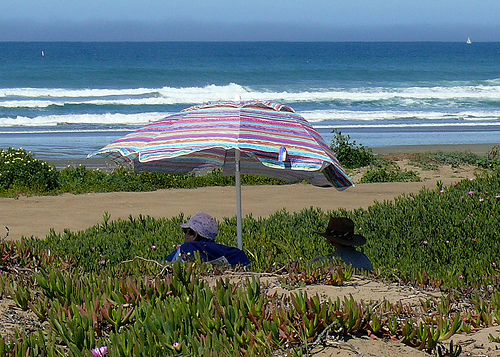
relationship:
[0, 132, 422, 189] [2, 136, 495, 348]
plants on beach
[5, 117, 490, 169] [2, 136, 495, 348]
shore on beach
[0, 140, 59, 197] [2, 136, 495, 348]
bush on beach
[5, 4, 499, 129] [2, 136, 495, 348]
ocean on beach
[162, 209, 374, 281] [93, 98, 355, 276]
people under an umbrella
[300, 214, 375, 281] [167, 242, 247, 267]
man wearing shirt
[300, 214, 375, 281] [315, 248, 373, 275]
man wearing shirt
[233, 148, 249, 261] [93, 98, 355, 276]
pole for an umbrella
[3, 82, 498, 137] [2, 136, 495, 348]
waves crashing on beach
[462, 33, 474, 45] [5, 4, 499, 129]
sail boat on ocean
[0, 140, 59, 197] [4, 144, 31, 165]
bush has white buds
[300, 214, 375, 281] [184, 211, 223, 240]
man wearing hat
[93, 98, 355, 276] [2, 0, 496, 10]
umbrella for sun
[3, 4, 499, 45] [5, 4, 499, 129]
sky over ocean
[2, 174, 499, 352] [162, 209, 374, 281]
plants are around people